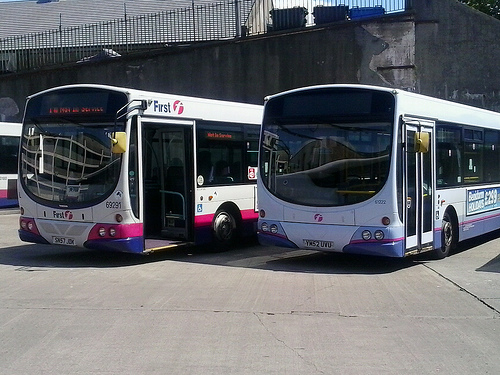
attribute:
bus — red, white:
[17, 82, 266, 261]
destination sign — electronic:
[39, 95, 111, 118]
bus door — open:
[141, 116, 198, 252]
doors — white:
[118, 117, 239, 247]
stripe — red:
[121, 206, 262, 242]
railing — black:
[6, 15, 398, 60]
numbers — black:
[102, 198, 125, 215]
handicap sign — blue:
[192, 205, 205, 212]